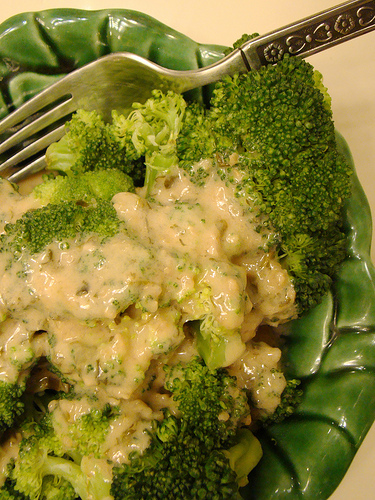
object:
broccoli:
[145, 42, 354, 318]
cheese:
[53, 237, 201, 335]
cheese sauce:
[0, 156, 301, 483]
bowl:
[0, 4, 375, 500]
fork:
[0, 0, 375, 189]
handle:
[237, 0, 375, 74]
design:
[335, 12, 356, 41]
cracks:
[33, 10, 77, 72]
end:
[348, 0, 375, 33]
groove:
[0, 5, 71, 84]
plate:
[0, 5, 375, 500]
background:
[0, 0, 374, 500]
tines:
[0, 51, 174, 190]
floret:
[209, 55, 354, 246]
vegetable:
[43, 108, 179, 181]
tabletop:
[0, 0, 375, 500]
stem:
[137, 148, 183, 202]